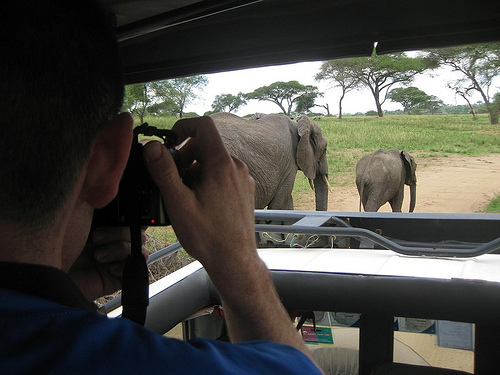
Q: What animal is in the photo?
A: Elephants.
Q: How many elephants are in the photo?
A: 2.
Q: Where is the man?
A: In a vehicle.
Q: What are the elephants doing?
A: Walking.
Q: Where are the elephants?
A: On a dirt road.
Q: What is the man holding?
A: A camera.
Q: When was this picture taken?
A: During the day.